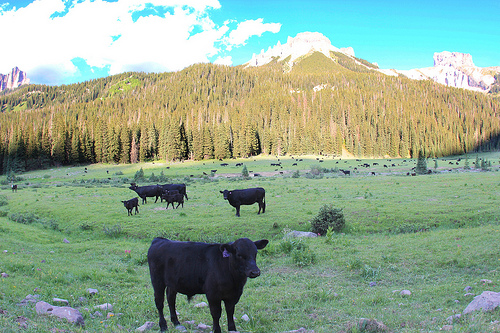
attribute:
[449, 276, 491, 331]
stones — large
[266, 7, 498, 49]
sky — vibrant, blue, overhead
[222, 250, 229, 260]
tag — blue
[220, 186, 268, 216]
cow — in the middle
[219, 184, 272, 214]
cow — in the middle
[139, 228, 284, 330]
black cattle — standing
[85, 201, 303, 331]
cow — black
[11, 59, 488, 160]
trees — tall, green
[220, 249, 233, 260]
tag — blue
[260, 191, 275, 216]
tail — long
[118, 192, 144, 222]
cow — black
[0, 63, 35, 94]
rock cluster — tall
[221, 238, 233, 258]
ears — black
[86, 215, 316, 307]
cow — in front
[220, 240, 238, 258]
tag — purple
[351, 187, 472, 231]
grass — green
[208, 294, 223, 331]
leg — cow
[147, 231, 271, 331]
cow — black, in the front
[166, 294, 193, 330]
leg — right leg, back leg